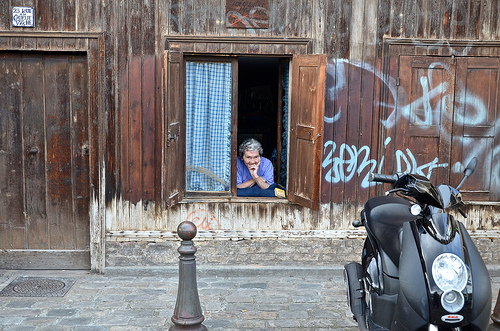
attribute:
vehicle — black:
[352, 164, 492, 302]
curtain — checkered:
[184, 61, 229, 193]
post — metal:
[154, 214, 209, 329]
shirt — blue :
[224, 159, 309, 201]